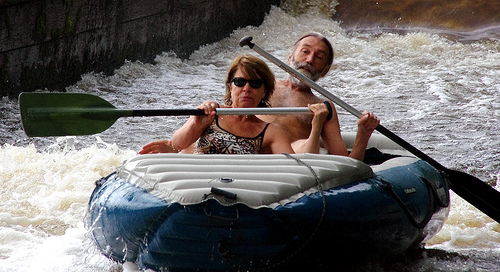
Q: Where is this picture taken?
A: River.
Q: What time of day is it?
A: Day time.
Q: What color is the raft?
A: Blue and white.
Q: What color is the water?
A: White.